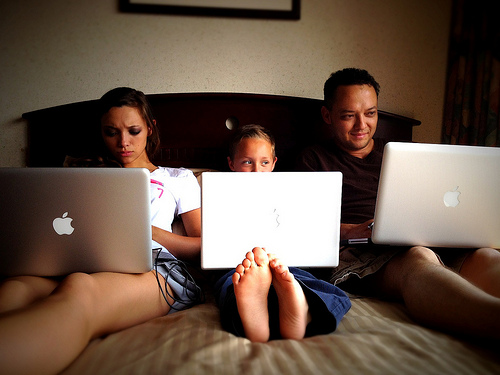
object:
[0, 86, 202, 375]
woman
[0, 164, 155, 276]
laptop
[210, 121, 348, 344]
girl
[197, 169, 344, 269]
laptop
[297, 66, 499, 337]
man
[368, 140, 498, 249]
laptop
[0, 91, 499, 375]
bed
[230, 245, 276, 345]
feet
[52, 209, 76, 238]
logo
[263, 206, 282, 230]
logo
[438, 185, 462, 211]
logo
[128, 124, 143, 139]
eyeshadow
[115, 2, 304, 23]
picture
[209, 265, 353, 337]
pants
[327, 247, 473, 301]
shorts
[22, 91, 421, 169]
headboard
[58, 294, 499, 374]
sheets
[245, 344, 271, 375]
stripes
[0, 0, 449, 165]
wall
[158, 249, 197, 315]
skirt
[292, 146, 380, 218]
shirt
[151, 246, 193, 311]
wires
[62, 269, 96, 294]
kneecaps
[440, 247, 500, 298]
legs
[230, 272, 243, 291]
toes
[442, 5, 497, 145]
curtain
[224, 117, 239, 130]
hole